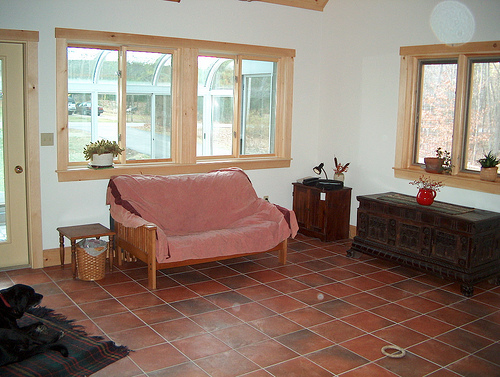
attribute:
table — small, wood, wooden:
[55, 222, 118, 272]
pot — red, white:
[416, 188, 436, 205]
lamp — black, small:
[312, 162, 329, 187]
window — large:
[67, 44, 173, 164]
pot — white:
[90, 152, 114, 168]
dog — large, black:
[0, 284, 68, 365]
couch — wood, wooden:
[105, 166, 304, 290]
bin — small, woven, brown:
[75, 238, 109, 279]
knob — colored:
[16, 165, 23, 175]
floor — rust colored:
[141, 293, 358, 369]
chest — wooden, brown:
[291, 184, 353, 238]